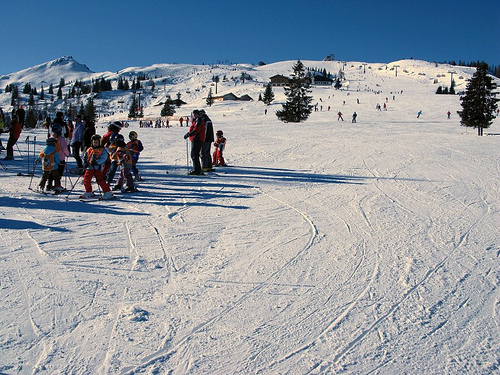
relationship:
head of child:
[86, 130, 104, 152] [83, 129, 110, 200]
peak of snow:
[46, 51, 90, 73] [0, 54, 499, 374]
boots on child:
[75, 184, 114, 205] [83, 129, 110, 200]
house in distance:
[264, 67, 291, 93] [221, 37, 429, 90]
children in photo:
[6, 82, 235, 204] [2, 39, 474, 352]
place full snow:
[2, 39, 474, 352] [255, 171, 431, 342]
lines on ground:
[96, 194, 215, 330] [60, 187, 429, 335]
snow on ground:
[255, 171, 431, 342] [60, 187, 429, 335]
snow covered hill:
[0, 54, 499, 374] [1, 44, 122, 99]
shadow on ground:
[12, 172, 373, 264] [60, 187, 429, 335]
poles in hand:
[178, 135, 190, 177] [182, 128, 194, 147]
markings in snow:
[107, 206, 380, 327] [290, 171, 462, 355]